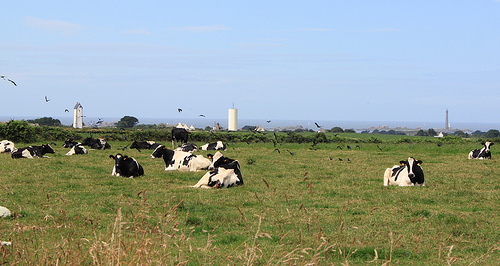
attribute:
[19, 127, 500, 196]
cattle — herd, lying down, seated, black, sitting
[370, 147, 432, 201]
cow — white, sitting, spotted, resting, alone, striped, black, lying down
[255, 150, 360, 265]
grass — brown, dry, green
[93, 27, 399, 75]
sky — blue, clear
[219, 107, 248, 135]
tower — white, tall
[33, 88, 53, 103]
bird — flying